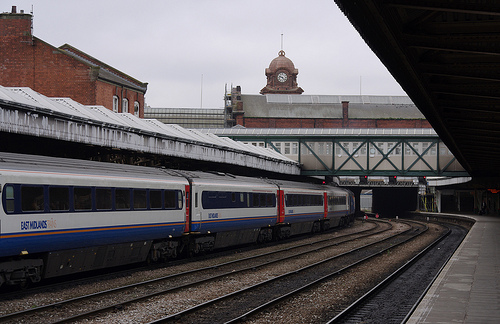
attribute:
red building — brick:
[1, 7, 148, 119]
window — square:
[68, 177, 103, 222]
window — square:
[14, 184, 46, 210]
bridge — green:
[217, 132, 468, 176]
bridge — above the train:
[247, 122, 474, 180]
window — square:
[264, 188, 279, 211]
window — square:
[19, 184, 188, 209]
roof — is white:
[2, 86, 299, 164]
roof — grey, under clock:
[235, 93, 428, 121]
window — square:
[371, 143, 411, 157]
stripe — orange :
[1, 200, 363, 238]